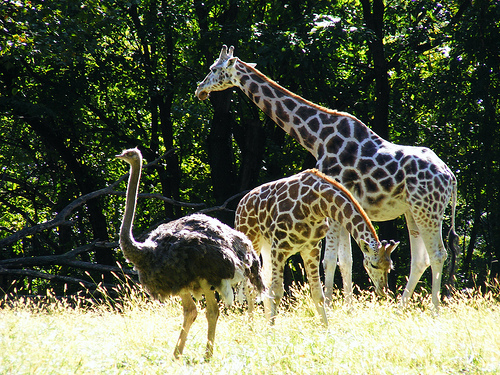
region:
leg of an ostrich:
[211, 303, 223, 329]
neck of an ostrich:
[121, 192, 136, 232]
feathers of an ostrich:
[184, 248, 219, 283]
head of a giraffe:
[373, 236, 384, 277]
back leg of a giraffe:
[426, 237, 446, 281]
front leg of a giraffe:
[311, 256, 320, 280]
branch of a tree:
[38, 212, 69, 232]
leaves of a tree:
[193, 150, 200, 169]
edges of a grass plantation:
[387, 335, 434, 360]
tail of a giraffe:
[452, 197, 457, 231]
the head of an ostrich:
[113, 143, 146, 170]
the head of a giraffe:
[356, 229, 411, 308]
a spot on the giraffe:
[336, 199, 353, 221]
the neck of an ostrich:
[108, 165, 148, 254]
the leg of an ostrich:
[197, 284, 222, 364]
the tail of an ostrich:
[233, 245, 275, 296]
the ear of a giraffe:
[221, 50, 240, 72]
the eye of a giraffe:
[366, 258, 383, 273]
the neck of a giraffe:
[317, 174, 382, 254]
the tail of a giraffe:
[441, 169, 463, 258]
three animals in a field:
[78, 22, 463, 335]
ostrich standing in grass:
[107, 137, 249, 363]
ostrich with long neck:
[98, 143, 255, 365]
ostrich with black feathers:
[116, 137, 248, 349]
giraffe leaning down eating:
[227, 160, 395, 326]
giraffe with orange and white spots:
[241, 177, 386, 342]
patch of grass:
[43, 291, 133, 366]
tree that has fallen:
[24, 167, 102, 312]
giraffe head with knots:
[188, 42, 257, 104]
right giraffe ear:
[356, 239, 372, 261]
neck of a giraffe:
[258, 77, 323, 110]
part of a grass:
[325, 323, 360, 357]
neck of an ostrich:
[119, 202, 129, 229]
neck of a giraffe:
[342, 209, 368, 254]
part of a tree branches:
[54, 230, 121, 287]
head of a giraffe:
[367, 250, 399, 295]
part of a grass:
[295, 310, 340, 350]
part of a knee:
[193, 300, 229, 332]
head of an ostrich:
[98, 111, 148, 192]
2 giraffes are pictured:
[253, 43, 495, 355]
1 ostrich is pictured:
[81, 127, 291, 357]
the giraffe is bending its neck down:
[226, 163, 398, 314]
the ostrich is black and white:
[96, 129, 251, 362]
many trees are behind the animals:
[1, 0, 488, 282]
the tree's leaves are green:
[3, 1, 488, 223]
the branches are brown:
[130, 25, 233, 200]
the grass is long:
[7, 255, 488, 373]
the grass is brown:
[3, 279, 463, 360]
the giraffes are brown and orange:
[185, 46, 499, 291]